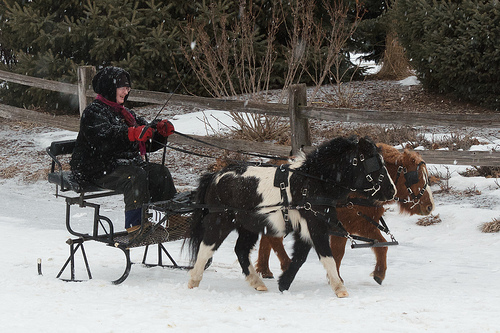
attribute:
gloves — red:
[123, 115, 200, 160]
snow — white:
[414, 242, 481, 291]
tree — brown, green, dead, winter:
[198, 19, 393, 84]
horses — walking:
[170, 140, 433, 290]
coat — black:
[57, 65, 169, 215]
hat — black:
[73, 59, 145, 106]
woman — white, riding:
[57, 57, 178, 236]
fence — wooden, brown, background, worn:
[170, 79, 436, 147]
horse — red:
[259, 142, 440, 238]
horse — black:
[173, 154, 368, 254]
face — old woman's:
[53, 64, 134, 126]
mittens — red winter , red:
[115, 103, 207, 158]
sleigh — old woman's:
[22, 143, 245, 261]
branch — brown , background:
[42, 29, 352, 92]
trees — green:
[2, 7, 489, 82]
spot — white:
[254, 176, 309, 214]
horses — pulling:
[29, 143, 434, 251]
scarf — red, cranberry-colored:
[87, 94, 155, 127]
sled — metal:
[53, 198, 199, 283]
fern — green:
[372, 11, 496, 100]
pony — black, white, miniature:
[203, 153, 416, 269]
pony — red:
[274, 142, 448, 225]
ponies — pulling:
[2, 122, 433, 250]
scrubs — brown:
[185, 4, 395, 177]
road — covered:
[9, 187, 492, 330]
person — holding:
[78, 69, 218, 178]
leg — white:
[154, 238, 242, 289]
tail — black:
[167, 173, 218, 264]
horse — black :
[194, 126, 382, 299]